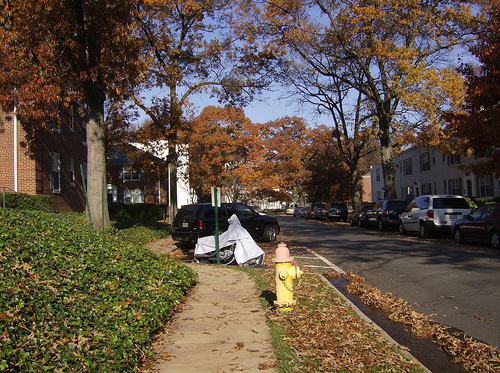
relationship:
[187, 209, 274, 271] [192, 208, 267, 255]
motorcycle covered with white cloth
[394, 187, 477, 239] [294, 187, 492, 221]
minivan parked at curb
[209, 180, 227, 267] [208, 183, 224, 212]
post with sign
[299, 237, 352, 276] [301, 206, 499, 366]
lines on street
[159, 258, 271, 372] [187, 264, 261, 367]
sidewalk with leaves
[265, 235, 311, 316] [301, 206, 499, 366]
fire hydrant near street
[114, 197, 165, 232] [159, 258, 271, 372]
shrubs near side walk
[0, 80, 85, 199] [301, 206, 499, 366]
house on street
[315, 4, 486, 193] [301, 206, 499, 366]
tree on a street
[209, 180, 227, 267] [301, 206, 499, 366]
traffic sign near street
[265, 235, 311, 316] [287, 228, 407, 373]
fire hydrant near curb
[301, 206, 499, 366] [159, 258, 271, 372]
ground sloping down sidewalk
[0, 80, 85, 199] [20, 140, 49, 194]
building seen edge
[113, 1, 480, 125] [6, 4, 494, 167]
sky through trees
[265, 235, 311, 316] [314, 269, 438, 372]
fire hydrant on curb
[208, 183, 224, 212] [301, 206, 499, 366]
sign on street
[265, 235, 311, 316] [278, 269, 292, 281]
hydrant has valve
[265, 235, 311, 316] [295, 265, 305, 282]
hydrant has valve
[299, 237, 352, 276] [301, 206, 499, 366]
street lined on sidewalk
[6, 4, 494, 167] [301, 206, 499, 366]
trees lining in street